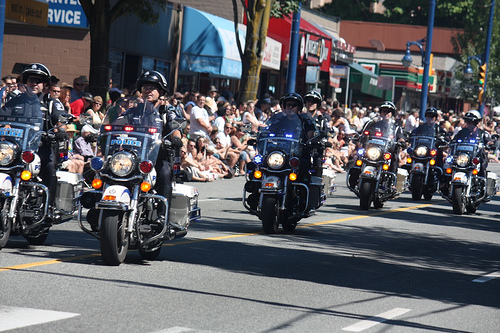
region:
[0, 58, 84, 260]
The man is on a motorcycle.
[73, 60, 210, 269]
The man is on a motorcycle.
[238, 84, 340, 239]
The man is on a motorcycle.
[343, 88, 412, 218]
The man is on a motorcycle.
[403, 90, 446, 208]
The man is on a motorcycle.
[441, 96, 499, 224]
The man is on a motorcycle.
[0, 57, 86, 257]
The man is wearing a helmet.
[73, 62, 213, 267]
The man is wearing a helmet.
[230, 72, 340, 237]
The man is wearing a helmet.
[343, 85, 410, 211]
The man is wearing a helmet.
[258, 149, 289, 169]
circular light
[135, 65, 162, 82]
black and white helmet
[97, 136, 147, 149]
police displayed in blue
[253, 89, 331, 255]
police officer on motorcycle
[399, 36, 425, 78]
hanging street lamp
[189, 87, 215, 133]
person in white shirttstanding with arms folded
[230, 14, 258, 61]
part of tree trunk and branch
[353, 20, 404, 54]
brown roof on building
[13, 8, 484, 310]
police motorcycles on parade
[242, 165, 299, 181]
bike's yellow lights on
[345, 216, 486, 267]
shadow of a tree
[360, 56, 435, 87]
store sign of a 7-11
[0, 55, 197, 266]
two motorcycles police riding side by side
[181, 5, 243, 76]
blue awning of a business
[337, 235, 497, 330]
dashed white lines on a street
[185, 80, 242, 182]
crowd watching the parade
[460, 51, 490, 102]
traffic and street lights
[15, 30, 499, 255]
a huge crowd of people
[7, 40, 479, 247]
a big public event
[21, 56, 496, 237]
cops driving through a parade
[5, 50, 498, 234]
seven cops driving down the street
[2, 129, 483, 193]
the lights on the motorcycle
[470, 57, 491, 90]
a green traffic light on a pole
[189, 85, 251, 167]
spectators watching the event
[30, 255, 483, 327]
the street is smooth and paved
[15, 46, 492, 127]
the cops are wearing helmets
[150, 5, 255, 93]
a blue canopy over the crowd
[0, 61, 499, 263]
the large group in the city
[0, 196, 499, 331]
the white lines on the road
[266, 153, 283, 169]
the white light on the motorcycle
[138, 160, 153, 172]
the red light on the motorcycle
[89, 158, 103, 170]
the blue light on the motorcycle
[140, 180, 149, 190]
the orange light on the motorcycle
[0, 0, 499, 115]
the row of buildings for businesses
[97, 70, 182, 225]
the policeman on the motorcycle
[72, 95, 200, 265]
the motorcycle the policeman is on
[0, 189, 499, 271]
the yellow line on the road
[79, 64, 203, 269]
Police officer riding motorcycle in motorcade.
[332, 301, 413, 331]
White stripe painted on pavement in middle of street.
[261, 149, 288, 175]
Headlight on front of motorcycle.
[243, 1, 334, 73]
Red store awning hanging above sidewalk.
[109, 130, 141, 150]
Blue and white lettering on front of motorcycle.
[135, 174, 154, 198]
Yellow light on front of motorcycle.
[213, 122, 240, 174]
Person in white shirt in crowd.